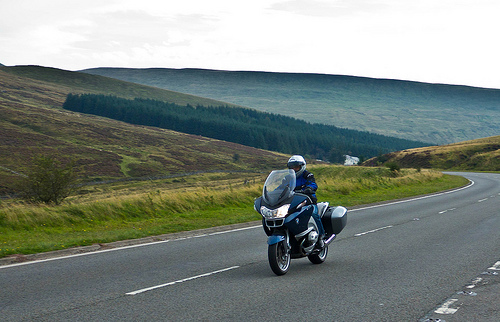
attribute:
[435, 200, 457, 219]
line — white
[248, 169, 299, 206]
windshield — clear, plastic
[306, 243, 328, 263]
tire — round, black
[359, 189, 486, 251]
stripe — white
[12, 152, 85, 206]
tree — small, young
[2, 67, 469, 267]
field — grass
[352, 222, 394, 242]
line — white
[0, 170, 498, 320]
road — asphalt, two lane